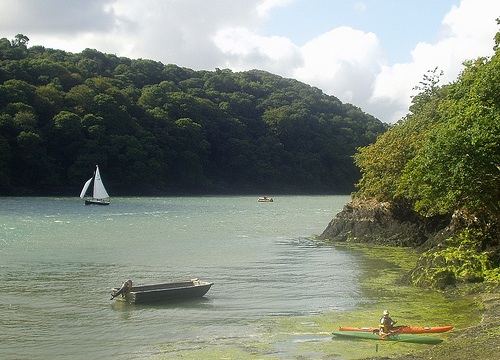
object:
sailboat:
[79, 164, 109, 205]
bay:
[0, 182, 499, 358]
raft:
[258, 196, 274, 202]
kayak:
[331, 326, 454, 345]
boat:
[110, 279, 214, 304]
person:
[379, 310, 396, 336]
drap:
[92, 164, 110, 199]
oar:
[379, 320, 398, 340]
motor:
[109, 279, 132, 301]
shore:
[375, 205, 500, 360]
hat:
[382, 309, 389, 316]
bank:
[0, 166, 359, 198]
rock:
[320, 219, 499, 290]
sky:
[1, 0, 500, 122]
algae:
[364, 285, 471, 327]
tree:
[47, 109, 87, 168]